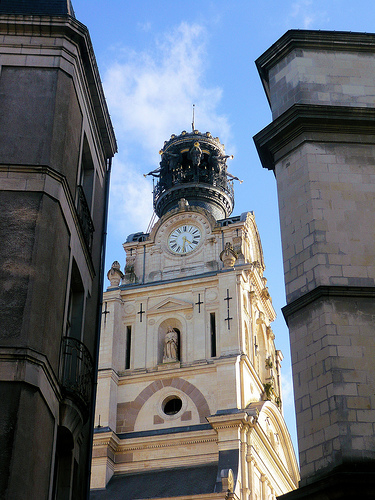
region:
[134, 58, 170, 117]
part of a cloud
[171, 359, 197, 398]
part of a cloud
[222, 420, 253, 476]
edge of a building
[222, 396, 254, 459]
edge of a building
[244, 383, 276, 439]
part of a wall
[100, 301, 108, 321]
an opening in the shape of a cross on the building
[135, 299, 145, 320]
an opening in the shape of a cross on the building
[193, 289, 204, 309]
an opening in the shape of a cross on the building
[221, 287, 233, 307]
an opening in the shape of a cross on the building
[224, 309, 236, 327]
an opening in the shape of a cross on the building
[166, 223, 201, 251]
a black white and gold clock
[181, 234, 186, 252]
the gold hand of a clock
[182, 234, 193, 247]
the gold hand of a clock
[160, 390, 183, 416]
a circle window in the building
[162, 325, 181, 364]
a tan statue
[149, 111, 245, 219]
Black and gold structure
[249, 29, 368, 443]
The brick is grey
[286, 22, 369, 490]
Building made of brick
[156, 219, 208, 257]
White, gold and black clock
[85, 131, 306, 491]
The clock tower is tall and narrow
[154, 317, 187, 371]
The statue is tan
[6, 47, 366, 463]
The clock tower is between two buildings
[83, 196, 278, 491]
The tower is tan and black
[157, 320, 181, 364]
The statue is a person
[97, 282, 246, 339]
Black crosses on tower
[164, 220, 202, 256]
clock on top of building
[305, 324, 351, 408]
brick detail on building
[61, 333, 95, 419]
wrought iron rail on building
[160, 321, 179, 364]
human statue on building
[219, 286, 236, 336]
crosses made of metal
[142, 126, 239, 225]
detailed top of building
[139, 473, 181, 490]
roofing material on ledge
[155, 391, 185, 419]
circular hole in building wall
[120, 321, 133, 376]
long skinny windows on building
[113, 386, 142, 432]
brick detail on clock tower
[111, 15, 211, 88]
see through clouds in the blue sky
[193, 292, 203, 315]
cross on the center building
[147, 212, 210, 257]
clock near the top of the beige building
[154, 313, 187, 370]
statue in an alcove of the building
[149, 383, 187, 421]
round opening on the side of the building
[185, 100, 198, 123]
metal pole coming out of the top of the roof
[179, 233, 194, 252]
gold hands on the clock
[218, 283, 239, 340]
two crosses together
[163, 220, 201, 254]
black roman numerals on clock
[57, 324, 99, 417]
wrought iron railing on side of building